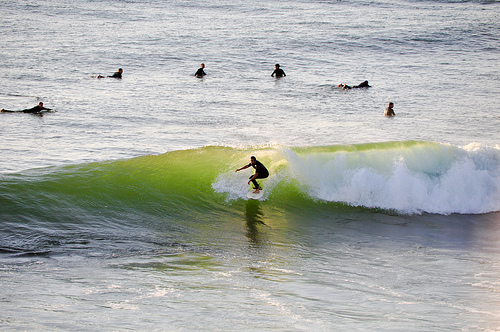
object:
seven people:
[0, 54, 401, 195]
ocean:
[13, 8, 495, 316]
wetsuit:
[341, 82, 371, 89]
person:
[338, 80, 372, 90]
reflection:
[151, 147, 308, 204]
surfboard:
[245, 178, 268, 200]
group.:
[0, 62, 405, 119]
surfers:
[194, 63, 208, 79]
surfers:
[271, 63, 287, 77]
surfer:
[95, 68, 124, 80]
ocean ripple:
[393, 282, 411, 294]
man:
[382, 101, 396, 117]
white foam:
[278, 136, 498, 218]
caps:
[283, 141, 499, 219]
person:
[0, 102, 57, 117]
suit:
[247, 160, 269, 189]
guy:
[235, 156, 270, 194]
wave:
[2, 140, 498, 216]